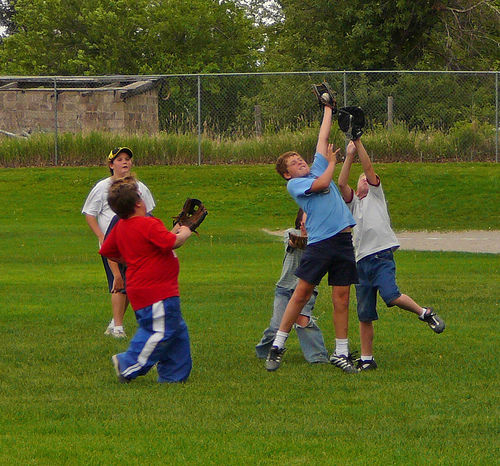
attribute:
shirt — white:
[342, 171, 398, 258]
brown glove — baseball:
[170, 193, 213, 239]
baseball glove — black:
[171, 196, 207, 233]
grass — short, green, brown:
[192, 347, 363, 458]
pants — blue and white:
[106, 291, 196, 385]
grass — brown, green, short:
[19, 381, 163, 448]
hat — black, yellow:
[103, 144, 136, 163]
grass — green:
[237, 366, 498, 465]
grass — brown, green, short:
[3, 388, 498, 464]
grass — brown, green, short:
[240, 369, 343, 464]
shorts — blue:
[294, 232, 357, 286]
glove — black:
[332, 101, 370, 140]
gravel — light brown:
[402, 229, 498, 254]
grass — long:
[181, 131, 274, 155]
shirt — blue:
[290, 182, 362, 235]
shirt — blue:
[265, 148, 352, 255]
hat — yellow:
[78, 129, 143, 163]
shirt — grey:
[327, 183, 413, 257]